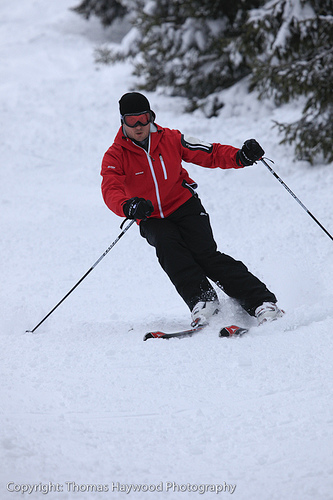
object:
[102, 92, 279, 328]
man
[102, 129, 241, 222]
jacket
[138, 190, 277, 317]
pants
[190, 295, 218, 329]
boot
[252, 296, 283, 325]
boot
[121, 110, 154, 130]
googles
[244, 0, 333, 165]
tree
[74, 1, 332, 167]
snow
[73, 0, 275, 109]
tree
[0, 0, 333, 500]
snow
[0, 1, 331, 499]
ground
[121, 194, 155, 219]
glove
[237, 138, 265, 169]
glove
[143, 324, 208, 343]
skies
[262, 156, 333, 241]
pole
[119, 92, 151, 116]
cap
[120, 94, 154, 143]
head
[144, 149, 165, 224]
zipper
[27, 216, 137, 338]
pole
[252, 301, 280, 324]
feet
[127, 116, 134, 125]
eye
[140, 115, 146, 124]
eye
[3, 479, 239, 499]
name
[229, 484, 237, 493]
letters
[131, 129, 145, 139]
mouth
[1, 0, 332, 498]
hill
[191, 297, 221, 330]
foot